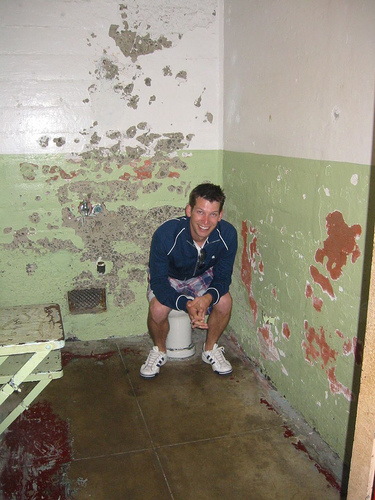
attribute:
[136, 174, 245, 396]
man — sitting, smiling, light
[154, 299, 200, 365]
toilet — white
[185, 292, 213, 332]
hand — folded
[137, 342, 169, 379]
shoe — white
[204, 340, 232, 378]
shoe — white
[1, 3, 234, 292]
wall — old, white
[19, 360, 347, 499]
floor — dirty, concrete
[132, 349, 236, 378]
shoes — white, blue